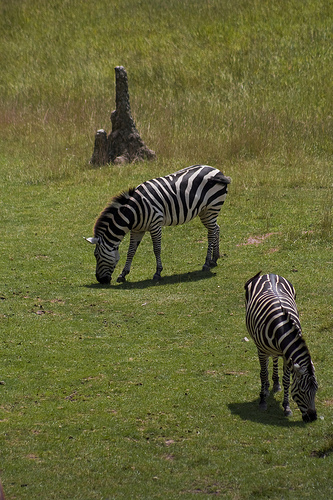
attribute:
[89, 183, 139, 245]
mohawk — striped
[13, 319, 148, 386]
grass field — green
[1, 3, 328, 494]
land scape — grassy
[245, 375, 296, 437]
zebra hooves — black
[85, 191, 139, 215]
mane — black, white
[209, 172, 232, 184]
tail — black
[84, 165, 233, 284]
zebra — small, black and white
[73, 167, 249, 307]
zebra — White, black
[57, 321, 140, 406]
grass — green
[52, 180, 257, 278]
zebra — striped, eating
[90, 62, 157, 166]
structure — weird